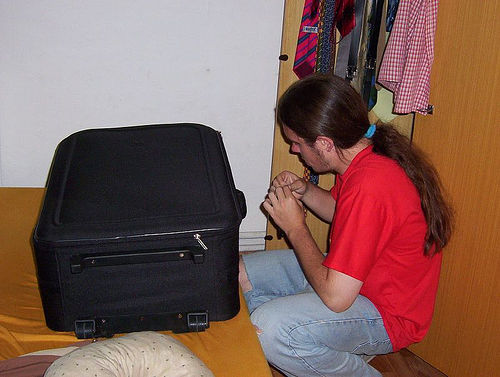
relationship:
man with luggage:
[279, 84, 412, 353] [66, 123, 241, 330]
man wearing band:
[279, 84, 412, 353] [358, 112, 381, 140]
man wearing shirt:
[279, 84, 412, 353] [335, 166, 437, 305]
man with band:
[279, 84, 412, 353] [358, 112, 381, 140]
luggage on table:
[66, 123, 241, 330] [13, 275, 45, 320]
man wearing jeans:
[279, 84, 412, 353] [279, 282, 312, 327]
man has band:
[279, 84, 412, 353] [358, 112, 381, 140]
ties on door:
[309, 10, 371, 46] [447, 19, 487, 62]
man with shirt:
[279, 84, 412, 353] [335, 166, 437, 305]